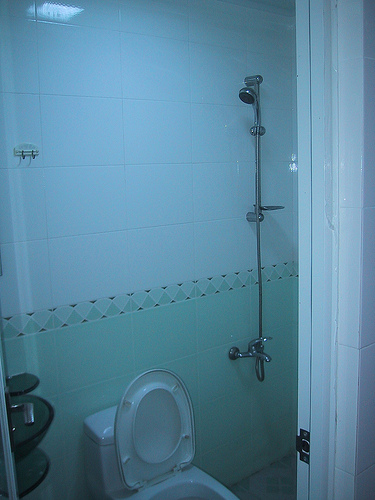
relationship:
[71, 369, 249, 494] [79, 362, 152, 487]
toilet has tank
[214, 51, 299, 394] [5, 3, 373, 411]
shower on wall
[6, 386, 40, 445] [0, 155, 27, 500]
knob on door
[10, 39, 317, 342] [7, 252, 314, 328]
tile has border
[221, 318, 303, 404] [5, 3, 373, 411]
faucet on wall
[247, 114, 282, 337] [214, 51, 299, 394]
hose on shower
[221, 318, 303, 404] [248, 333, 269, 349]
faucet reflects light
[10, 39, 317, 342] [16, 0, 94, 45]
tile reflects light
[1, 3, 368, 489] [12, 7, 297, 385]
bathroom has tiles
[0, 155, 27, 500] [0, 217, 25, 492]
door can lock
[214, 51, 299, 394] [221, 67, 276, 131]
shower has shower head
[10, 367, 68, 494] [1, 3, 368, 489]
holder in bathroom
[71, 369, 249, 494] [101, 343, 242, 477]
toilet has seat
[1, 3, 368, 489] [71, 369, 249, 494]
bathroom has toilet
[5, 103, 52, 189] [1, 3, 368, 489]
hook in bathroom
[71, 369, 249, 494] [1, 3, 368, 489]
toilet in bathroom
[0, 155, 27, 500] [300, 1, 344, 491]
door has frame